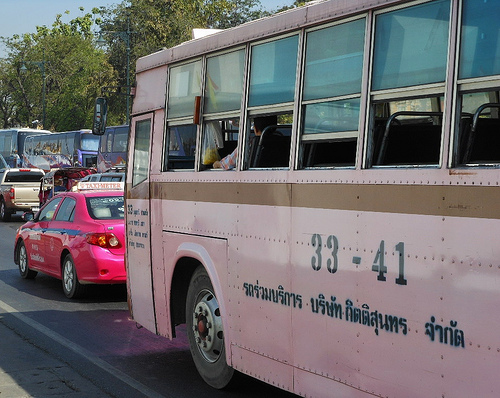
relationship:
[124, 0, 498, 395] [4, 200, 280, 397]
bus on a street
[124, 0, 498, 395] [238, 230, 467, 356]
bus has writing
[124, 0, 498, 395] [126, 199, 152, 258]
bus has writing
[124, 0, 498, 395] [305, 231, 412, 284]
bus has 33-41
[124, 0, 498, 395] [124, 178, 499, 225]
bus has gold stripe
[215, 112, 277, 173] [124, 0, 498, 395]
person in bus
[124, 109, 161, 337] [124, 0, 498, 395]
door on bus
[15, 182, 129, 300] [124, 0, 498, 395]
taxi in front of bus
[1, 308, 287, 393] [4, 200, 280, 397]
shadow on street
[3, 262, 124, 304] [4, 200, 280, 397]
shadow on street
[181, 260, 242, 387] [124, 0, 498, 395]
tire on bus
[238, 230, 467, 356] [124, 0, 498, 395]
writing on bus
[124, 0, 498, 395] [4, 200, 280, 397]
bus on street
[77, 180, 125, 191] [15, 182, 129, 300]
sign on taxi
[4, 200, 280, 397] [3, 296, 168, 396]
street has white line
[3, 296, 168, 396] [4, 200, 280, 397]
white line on street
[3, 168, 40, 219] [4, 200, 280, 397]
truck on street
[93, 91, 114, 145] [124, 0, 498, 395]
mirror on bus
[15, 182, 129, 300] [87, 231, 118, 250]
taxi has rear lights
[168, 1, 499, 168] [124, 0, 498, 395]
windows on bus